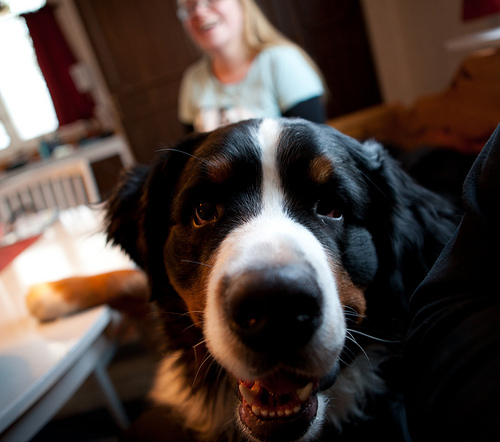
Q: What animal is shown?
A: A dog.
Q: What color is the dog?
A: Black, brown, and white.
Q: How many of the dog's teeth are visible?
A: Eight.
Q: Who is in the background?
A: A woman.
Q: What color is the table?
A: White.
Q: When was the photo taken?
A: During the day.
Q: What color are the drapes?
A: Red.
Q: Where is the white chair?
A: At the end of the table in front of the window.